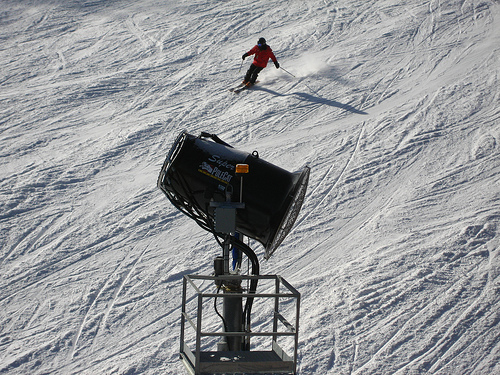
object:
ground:
[0, 0, 500, 375]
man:
[240, 37, 280, 89]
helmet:
[259, 37, 266, 44]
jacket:
[246, 45, 277, 68]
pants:
[244, 63, 264, 84]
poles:
[239, 60, 244, 73]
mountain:
[0, 0, 500, 375]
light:
[155, 130, 311, 260]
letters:
[208, 155, 220, 162]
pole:
[279, 66, 296, 78]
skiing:
[219, 69, 274, 96]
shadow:
[248, 84, 370, 116]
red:
[260, 52, 268, 60]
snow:
[0, 0, 500, 375]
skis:
[234, 79, 260, 93]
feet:
[246, 81, 253, 86]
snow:
[295, 37, 332, 78]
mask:
[258, 42, 266, 47]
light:
[236, 163, 249, 173]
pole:
[240, 177, 243, 204]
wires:
[159, 162, 259, 352]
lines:
[330, 236, 494, 334]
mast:
[213, 237, 244, 352]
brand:
[198, 155, 234, 185]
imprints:
[416, 2, 487, 47]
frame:
[176, 273, 301, 375]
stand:
[176, 202, 301, 375]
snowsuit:
[243, 45, 278, 83]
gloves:
[242, 54, 248, 61]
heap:
[0, 0, 163, 137]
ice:
[0, 58, 140, 146]